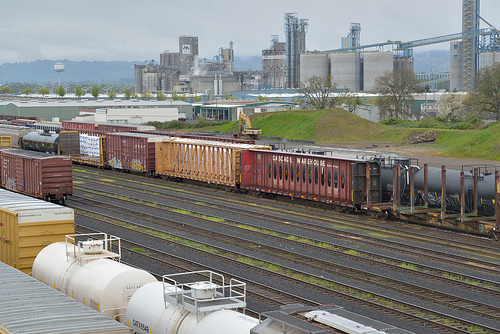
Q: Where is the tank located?
A: On the track.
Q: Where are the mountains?
A: Background.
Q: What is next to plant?
A: Tall buildings.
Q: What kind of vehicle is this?
A: Train.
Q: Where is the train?
A: Train tracks.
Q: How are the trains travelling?
A: Train tracks.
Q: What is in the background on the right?
A: Industrial buildings.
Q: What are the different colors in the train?
A: Red , orange, brown, white and yellow.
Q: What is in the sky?
A: Clouds.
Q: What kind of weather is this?
A: Overcast.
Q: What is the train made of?
A: Metal and steel.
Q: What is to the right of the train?
A: Grass covered small hills.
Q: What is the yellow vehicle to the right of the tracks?
A: Construction vehicle.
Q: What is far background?
A: Forested hills.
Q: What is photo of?
A: Train yard with cargo train cars.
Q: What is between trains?
A: Train tracks.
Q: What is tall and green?
A: Hills with grass.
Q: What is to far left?
A: Two white fuel tankers.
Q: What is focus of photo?
A: Factory and train yard.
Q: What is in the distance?
A: Mountains.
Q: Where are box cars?
A: In trail yard.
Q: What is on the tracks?
A: Trains.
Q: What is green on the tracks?
A: Grass is in between the tracks.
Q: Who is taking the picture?
A: A photographer.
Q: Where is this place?
A: A train yard.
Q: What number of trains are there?
A: There are 4 trains.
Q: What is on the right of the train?
A: A dirt grass hill.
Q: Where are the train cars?
A: On the tracks.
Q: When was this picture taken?
A: Daytime.